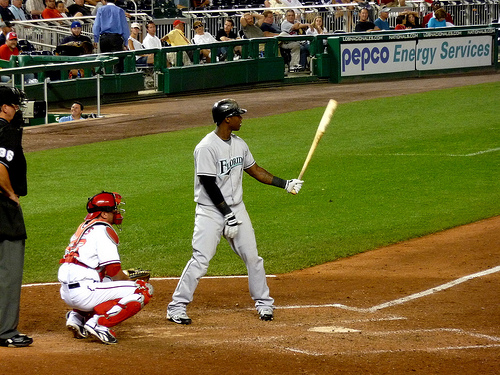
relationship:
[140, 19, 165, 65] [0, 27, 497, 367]
fan watching game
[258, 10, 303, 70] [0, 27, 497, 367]
fan watching game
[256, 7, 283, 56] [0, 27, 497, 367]
fan watching game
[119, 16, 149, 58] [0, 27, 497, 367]
fan watching game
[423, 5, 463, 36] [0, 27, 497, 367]
fan watching game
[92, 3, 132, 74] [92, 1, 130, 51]
man wearing man shirt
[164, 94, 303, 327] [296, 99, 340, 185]
batter holding bat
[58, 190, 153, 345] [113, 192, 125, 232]
catcher wearing mask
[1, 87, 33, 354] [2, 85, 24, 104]
baseball umpire wearing black hat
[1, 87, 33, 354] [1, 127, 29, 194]
baseball umpire wearing black shirt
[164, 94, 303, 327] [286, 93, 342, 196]
batter holding baseball bat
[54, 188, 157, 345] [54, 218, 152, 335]
catcher wearing uniform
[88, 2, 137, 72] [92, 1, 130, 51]
man in man shirt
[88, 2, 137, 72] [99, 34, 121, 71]
man in pants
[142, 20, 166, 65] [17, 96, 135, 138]
fan sitting in dugout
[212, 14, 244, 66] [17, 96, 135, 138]
man sitting in dugout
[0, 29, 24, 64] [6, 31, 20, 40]
man in hat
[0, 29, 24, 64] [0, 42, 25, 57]
man in shirt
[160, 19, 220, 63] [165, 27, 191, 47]
fans in shirt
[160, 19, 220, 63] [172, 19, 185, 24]
fans in hat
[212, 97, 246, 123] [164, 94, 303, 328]
baseball cap on batter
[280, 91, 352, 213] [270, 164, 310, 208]
baseball bat held in hand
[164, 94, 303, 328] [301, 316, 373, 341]
batter on home base